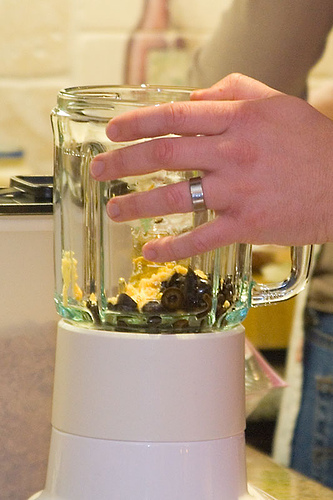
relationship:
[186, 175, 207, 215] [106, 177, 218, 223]
ring on finger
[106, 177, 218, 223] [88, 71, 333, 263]
finger on hand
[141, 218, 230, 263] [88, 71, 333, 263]
finger on hand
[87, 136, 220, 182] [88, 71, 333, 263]
finger on hand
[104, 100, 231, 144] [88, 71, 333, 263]
finger on hand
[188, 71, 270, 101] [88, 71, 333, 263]
thumb on hand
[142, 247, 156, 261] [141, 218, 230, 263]
fingernail on finger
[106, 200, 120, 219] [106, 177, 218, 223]
fingernail on finger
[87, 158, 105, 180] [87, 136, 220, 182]
fingernail on finger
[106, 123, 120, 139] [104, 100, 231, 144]
fingernail on finger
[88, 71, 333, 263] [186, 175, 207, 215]
hand wearing ring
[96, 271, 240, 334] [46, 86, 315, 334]
olives in blender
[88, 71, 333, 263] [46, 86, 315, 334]
hand on blender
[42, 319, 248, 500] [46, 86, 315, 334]
bottom of blender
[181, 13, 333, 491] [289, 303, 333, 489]
person wearing jeans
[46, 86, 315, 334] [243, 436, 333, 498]
blender on counter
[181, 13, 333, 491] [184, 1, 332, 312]
person wearing shirt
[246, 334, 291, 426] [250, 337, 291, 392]
bag has zipper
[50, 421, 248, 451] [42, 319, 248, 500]
seam on blender bottom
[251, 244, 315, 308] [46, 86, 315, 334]
handle on blender